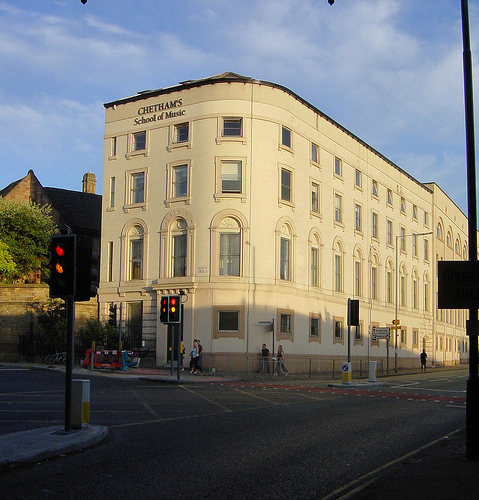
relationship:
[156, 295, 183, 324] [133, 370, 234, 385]
stoplight on corner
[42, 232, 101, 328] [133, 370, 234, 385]
stop light on corner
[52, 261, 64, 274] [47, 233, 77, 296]
light on stop light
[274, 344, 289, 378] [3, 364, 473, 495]
woman on street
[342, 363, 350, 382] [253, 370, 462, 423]
box on median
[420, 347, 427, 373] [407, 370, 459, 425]
guy walking down street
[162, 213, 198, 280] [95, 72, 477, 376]
window on building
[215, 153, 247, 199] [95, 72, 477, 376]
window on building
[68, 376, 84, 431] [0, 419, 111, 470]
box on median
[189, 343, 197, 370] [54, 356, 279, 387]
lady walking on sidewalk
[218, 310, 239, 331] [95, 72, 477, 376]
window on building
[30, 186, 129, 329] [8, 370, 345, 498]
stop light on street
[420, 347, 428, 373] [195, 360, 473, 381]
guy walking on sidewalk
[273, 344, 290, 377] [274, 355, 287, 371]
girl wearing pants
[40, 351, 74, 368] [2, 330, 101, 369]
bike leaning on a fence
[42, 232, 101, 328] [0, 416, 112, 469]
stop light on island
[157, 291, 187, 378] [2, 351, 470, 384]
traffic lights on sidewalk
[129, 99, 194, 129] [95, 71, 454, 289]
words on building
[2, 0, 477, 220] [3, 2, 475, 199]
clouds in blue sky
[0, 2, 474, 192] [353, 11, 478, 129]
sky with clouds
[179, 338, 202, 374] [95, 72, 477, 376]
people by building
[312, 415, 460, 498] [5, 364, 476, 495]
line on road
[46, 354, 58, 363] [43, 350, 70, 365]
tire on bike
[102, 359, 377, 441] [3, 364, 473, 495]
lines in street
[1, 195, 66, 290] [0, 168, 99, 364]
tree near building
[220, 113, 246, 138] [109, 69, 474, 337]
window on building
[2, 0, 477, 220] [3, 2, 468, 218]
clouds in sky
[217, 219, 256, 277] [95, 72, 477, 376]
window on building